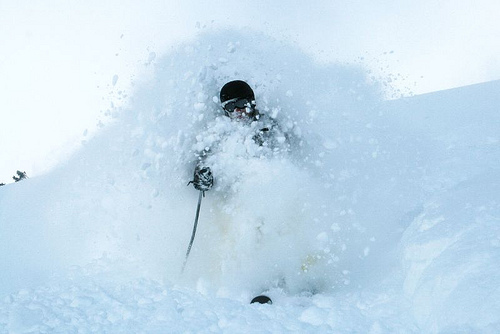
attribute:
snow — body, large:
[0, 78, 493, 332]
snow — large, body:
[416, 117, 468, 244]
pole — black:
[179, 166, 212, 277]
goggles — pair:
[204, 70, 263, 125]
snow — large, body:
[337, 229, 449, 311]